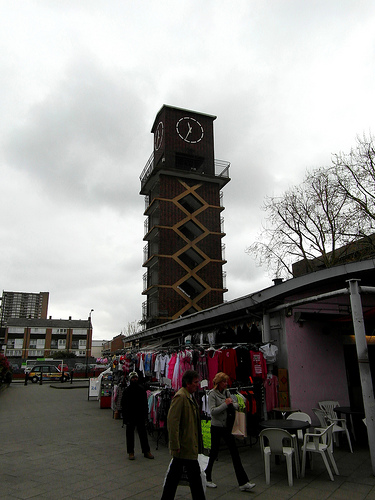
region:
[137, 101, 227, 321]
large dark tower with a brown diamond pattern down its center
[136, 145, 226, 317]
railings running along exterior of tower levels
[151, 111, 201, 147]
clocks along sides of tower are brightly outlined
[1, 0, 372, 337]
sky is cloudy and slightly ominous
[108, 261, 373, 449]
building with clothing set on racks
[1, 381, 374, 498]
area paved with grey rectangular bricks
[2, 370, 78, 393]
black low posts at end of paved area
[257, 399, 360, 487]
plastic chairs set around small round tables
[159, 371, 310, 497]
man and woman walking past table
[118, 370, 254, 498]
lone man seemingly watching walking couple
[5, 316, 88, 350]
THAT IS A HOUSE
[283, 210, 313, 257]
THAT IS A TREE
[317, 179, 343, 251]
THAT IS A TREE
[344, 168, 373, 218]
THAT IS A TREE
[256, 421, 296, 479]
THAT IS A CHAIR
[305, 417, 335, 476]
THAT IS A CHAIR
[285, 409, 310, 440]
THAT IS A CHAIR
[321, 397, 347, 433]
THAT IS A CHAIR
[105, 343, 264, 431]
rack of clothing outside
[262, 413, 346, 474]
chairs and table outside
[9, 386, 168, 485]
walk for pedestrians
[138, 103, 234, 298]
tower with clocks on it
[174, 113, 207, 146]
face of clock on side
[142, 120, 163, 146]
face of clock on other side of tower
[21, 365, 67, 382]
vehicle on side of street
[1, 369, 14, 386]
bush on the sidewalk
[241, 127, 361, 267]
branches on a tree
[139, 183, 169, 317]
sections of the tower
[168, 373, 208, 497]
that is a prson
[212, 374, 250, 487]
that is a prson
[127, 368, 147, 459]
that is a prson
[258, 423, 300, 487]
that is a chair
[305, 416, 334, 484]
that is a chair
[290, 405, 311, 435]
that is a chair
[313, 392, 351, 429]
that is a chair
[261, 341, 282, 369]
that is a dress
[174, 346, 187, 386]
that is a dress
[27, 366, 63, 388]
that is a car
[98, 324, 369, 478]
A large outdoor shopping area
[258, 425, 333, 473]
Tan chairs around a table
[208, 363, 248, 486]
A woman walking with brown shopping bag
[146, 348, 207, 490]
A man with a white shopping bag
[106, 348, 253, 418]
A long rack of clothes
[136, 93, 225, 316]
A tall tower with a clock at top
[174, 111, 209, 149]
A round white rimmed clock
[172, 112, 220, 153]
White hour and minute hands on clock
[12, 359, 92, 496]
Square tiles on ground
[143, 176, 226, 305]
A brown tower with light brown diamond design